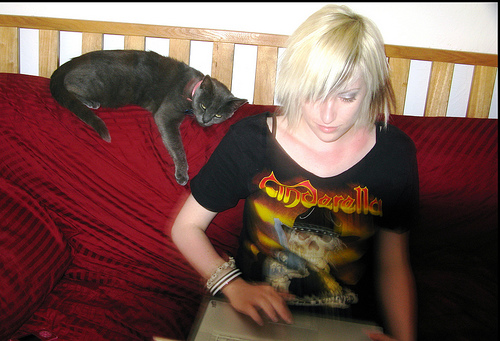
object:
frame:
[0, 15, 499, 121]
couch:
[0, 72, 499, 339]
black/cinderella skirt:
[225, 134, 265, 175]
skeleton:
[282, 228, 341, 267]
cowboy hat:
[290, 203, 341, 239]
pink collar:
[190, 76, 206, 97]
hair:
[273, 3, 396, 139]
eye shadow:
[333, 93, 363, 100]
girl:
[170, 5, 424, 341]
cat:
[48, 46, 251, 187]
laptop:
[151, 300, 382, 340]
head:
[274, 4, 382, 144]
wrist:
[216, 274, 253, 297]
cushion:
[0, 70, 499, 341]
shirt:
[186, 112, 421, 323]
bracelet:
[206, 269, 244, 296]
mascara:
[338, 97, 358, 104]